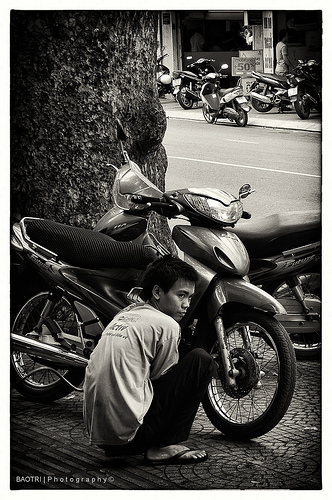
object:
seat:
[12, 209, 161, 278]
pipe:
[15, 322, 90, 375]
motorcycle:
[17, 177, 297, 447]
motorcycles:
[249, 57, 321, 117]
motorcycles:
[171, 54, 227, 109]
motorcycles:
[286, 56, 320, 119]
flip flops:
[142, 440, 210, 467]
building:
[154, 11, 321, 75]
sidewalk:
[4, 323, 323, 488]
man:
[85, 249, 222, 467]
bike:
[88, 113, 323, 363]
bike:
[198, 73, 253, 128]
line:
[161, 152, 322, 181]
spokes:
[216, 327, 272, 416]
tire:
[203, 306, 295, 438]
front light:
[183, 190, 247, 224]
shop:
[152, 10, 323, 95]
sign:
[229, 56, 257, 75]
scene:
[12, 11, 327, 492]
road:
[168, 119, 323, 227]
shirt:
[82, 299, 181, 453]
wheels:
[9, 278, 87, 404]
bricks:
[239, 448, 314, 490]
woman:
[273, 34, 293, 83]